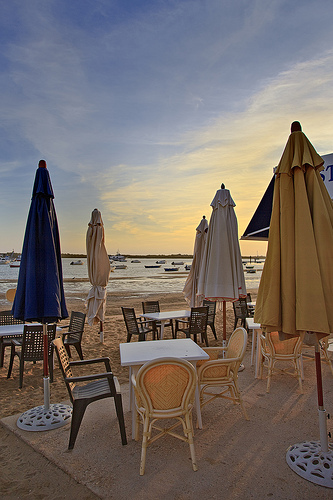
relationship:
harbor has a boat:
[3, 252, 265, 287] [147, 263, 165, 271]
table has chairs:
[121, 339, 211, 368] [200, 326, 255, 423]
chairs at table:
[200, 326, 255, 423] [121, 339, 211, 368]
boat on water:
[147, 263, 165, 271] [3, 253, 267, 282]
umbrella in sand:
[0, 162, 57, 322] [3, 288, 264, 318]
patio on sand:
[3, 366, 332, 499] [3, 288, 264, 318]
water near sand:
[3, 253, 267, 282] [3, 288, 264, 318]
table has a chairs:
[121, 339, 211, 368] [200, 326, 255, 423]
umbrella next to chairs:
[0, 162, 57, 322] [200, 326, 255, 423]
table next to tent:
[121, 339, 211, 368] [244, 162, 332, 242]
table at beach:
[121, 339, 211, 368] [2, 288, 332, 411]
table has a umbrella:
[121, 339, 211, 368] [0, 162, 57, 322]